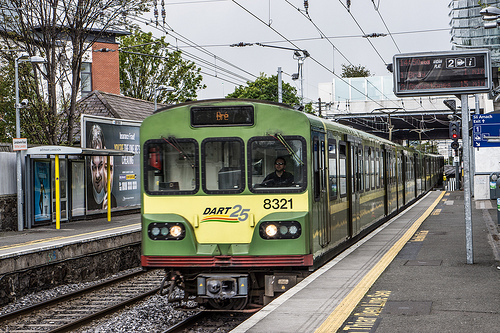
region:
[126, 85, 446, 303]
green and yellow train in station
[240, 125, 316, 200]
conductor seated behind window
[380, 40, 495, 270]
rectangular and modern sign on narrow pole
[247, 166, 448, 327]
white, grey and yellow edging on platform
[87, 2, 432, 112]
sets of wires over the train and tracks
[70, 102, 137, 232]
large sign on wall by platform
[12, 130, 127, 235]
small shelter for waiting passengers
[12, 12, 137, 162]
white and brick building behind station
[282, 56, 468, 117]
overpass with glass panels on top of train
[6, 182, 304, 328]
lower elevation covered in rails and gravel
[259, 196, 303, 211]
black numbers 8321 on front of train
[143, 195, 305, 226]
yellow signage on front of train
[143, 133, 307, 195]
three windows on engine of train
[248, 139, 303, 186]
train engineer driving train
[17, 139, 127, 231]
covered train stop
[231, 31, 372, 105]
wires above train running train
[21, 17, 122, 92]
red bricked building near train tracks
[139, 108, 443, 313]
green and yellow train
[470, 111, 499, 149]
blue and white sign near amtrak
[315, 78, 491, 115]
walkway above train tracks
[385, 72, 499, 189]
An old green train.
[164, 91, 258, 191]
An old green train.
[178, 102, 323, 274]
An old green train.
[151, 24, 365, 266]
An old green train.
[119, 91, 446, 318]
Green and yellow train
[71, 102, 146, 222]
Advertising billboard in train station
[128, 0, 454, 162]
Electrical cables above the train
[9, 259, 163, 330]
Train tracks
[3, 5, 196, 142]
Trees and a building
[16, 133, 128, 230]
Train station waiting shelter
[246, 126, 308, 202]
Train conductor behind a window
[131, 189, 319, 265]
Headlights on a train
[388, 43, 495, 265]
Information sign at train station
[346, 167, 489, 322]
Train station platform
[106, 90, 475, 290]
the train is green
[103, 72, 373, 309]
train is at the platform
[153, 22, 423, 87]
the sky is overcast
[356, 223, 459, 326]
platform has line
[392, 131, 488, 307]
the platform is empty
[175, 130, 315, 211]
a man driving the train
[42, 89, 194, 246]
ads at the platform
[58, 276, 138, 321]
the train tracks are rusty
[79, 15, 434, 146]
electric wires at train station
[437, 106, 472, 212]
traffic light is on